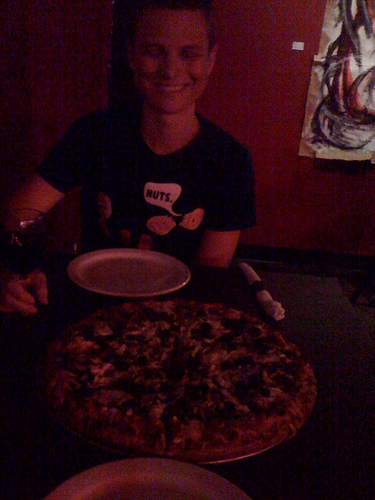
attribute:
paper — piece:
[295, 0, 373, 158]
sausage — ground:
[195, 323, 216, 340]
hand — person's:
[3, 268, 54, 318]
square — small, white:
[282, 26, 308, 62]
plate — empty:
[67, 238, 198, 309]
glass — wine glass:
[2, 203, 52, 279]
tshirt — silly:
[37, 101, 268, 255]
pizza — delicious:
[49, 292, 327, 453]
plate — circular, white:
[67, 241, 195, 305]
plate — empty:
[64, 245, 192, 300]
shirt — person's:
[36, 104, 257, 268]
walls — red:
[233, 49, 279, 107]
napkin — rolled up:
[195, 248, 320, 352]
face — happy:
[122, 11, 254, 140]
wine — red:
[13, 204, 55, 271]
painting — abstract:
[295, 23, 363, 160]